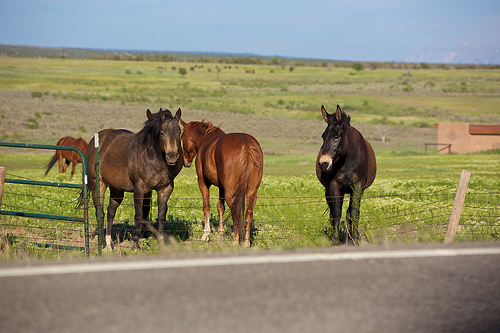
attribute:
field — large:
[20, 57, 491, 141]